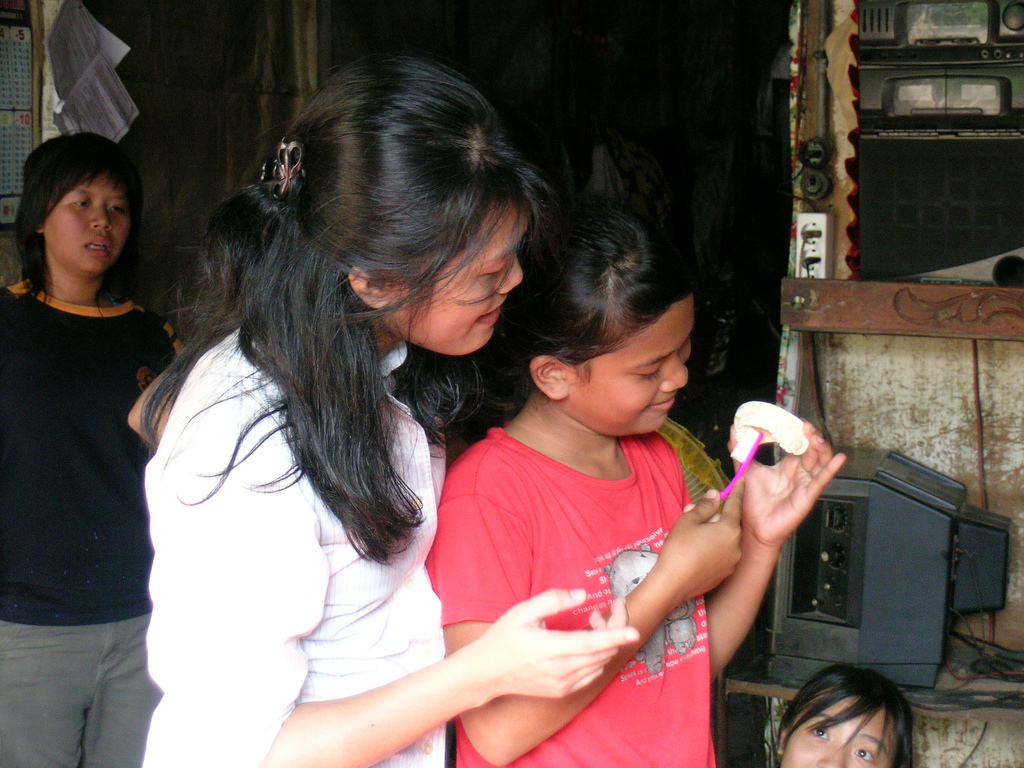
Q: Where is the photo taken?
A: The living room.